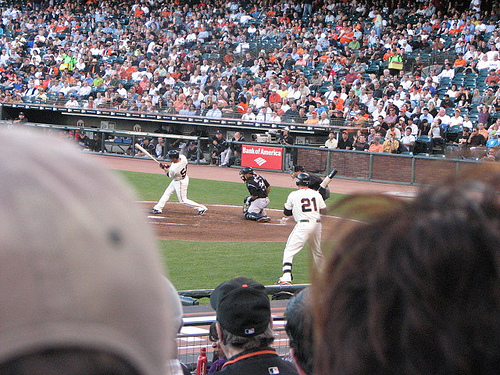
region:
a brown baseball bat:
[130, 140, 159, 164]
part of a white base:
[145, 210, 162, 222]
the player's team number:
[299, 195, 324, 217]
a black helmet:
[165, 149, 181, 159]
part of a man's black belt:
[299, 218, 311, 227]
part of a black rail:
[263, 278, 309, 293]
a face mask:
[235, 170, 250, 181]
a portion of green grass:
[160, 230, 270, 285]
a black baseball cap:
[205, 275, 271, 340]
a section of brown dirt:
[167, 213, 272, 240]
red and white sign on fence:
[237, 141, 287, 173]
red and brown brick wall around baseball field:
[292, 142, 498, 194]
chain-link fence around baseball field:
[1, 116, 295, 174]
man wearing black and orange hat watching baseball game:
[186, 274, 308, 374]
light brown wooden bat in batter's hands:
[132, 140, 168, 171]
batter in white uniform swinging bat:
[132, 142, 209, 219]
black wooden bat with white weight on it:
[307, 166, 339, 212]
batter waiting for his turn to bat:
[275, 167, 338, 284]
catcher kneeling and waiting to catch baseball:
[237, 161, 274, 223]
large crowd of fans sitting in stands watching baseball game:
[0, 0, 498, 162]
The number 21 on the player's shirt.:
[300, 197, 317, 214]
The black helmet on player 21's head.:
[295, 172, 307, 184]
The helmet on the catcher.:
[238, 166, 254, 175]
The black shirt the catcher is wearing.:
[245, 177, 266, 193]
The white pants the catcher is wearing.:
[240, 200, 270, 214]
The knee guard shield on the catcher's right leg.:
[245, 210, 260, 220]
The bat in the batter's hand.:
[132, 145, 167, 170]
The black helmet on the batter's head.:
[170, 148, 173, 156]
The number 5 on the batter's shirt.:
[176, 168, 187, 178]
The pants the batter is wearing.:
[157, 183, 199, 205]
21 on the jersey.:
[295, 193, 327, 224]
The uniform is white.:
[271, 180, 335, 292]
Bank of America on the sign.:
[233, 143, 292, 173]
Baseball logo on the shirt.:
[251, 360, 290, 374]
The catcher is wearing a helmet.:
[236, 160, 266, 188]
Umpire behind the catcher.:
[284, 158, 342, 210]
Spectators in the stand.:
[1, 0, 499, 157]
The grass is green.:
[158, 233, 298, 278]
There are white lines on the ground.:
[113, 176, 380, 243]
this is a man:
[268, 160, 353, 288]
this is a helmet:
[293, 169, 315, 179]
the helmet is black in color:
[297, 172, 312, 178]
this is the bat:
[130, 140, 160, 171]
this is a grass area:
[201, 250, 246, 270]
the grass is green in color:
[203, 240, 264, 275]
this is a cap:
[212, 271, 268, 336]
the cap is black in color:
[223, 295, 255, 315]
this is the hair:
[382, 234, 451, 310]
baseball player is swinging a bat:
[134, 143, 209, 219]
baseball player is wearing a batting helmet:
[151, 147, 208, 217]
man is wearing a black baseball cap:
[201, 275, 298, 374]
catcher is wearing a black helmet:
[236, 166, 270, 223]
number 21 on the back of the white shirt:
[286, 186, 328, 221]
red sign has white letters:
[239, 141, 282, 170]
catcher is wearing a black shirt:
[239, 164, 273, 224]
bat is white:
[134, 143, 169, 170]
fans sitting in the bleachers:
[1, 1, 498, 160]